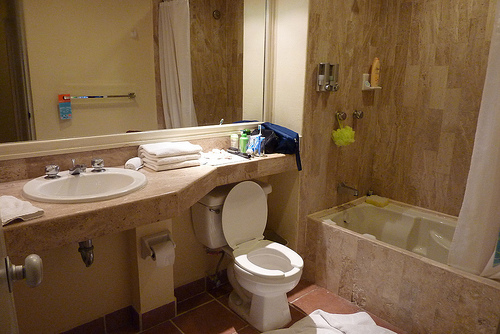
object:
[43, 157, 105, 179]
faucet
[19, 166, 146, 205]
sink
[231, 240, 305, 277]
seat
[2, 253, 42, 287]
knob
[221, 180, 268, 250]
lid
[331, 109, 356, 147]
loofah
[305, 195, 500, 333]
tub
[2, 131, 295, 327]
counter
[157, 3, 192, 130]
shower curtain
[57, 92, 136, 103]
rack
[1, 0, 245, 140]
wall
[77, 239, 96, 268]
sink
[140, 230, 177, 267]
toilet paper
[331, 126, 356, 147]
sponge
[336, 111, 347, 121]
handle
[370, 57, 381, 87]
shampoo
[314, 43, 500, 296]
shower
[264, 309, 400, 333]
towel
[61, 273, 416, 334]
floor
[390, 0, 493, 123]
wall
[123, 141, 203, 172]
towels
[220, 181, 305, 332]
toilet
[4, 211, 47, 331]
door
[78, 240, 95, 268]
pipe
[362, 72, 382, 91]
shelf